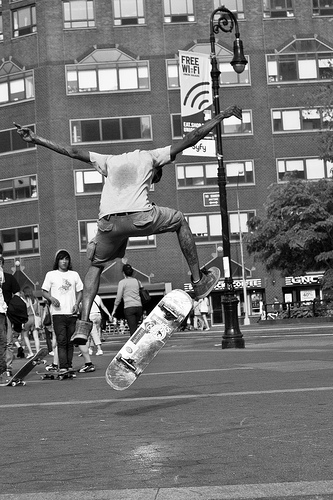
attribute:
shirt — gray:
[86, 133, 179, 232]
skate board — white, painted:
[104, 288, 192, 390]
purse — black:
[137, 284, 155, 307]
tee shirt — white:
[46, 270, 81, 310]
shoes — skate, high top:
[188, 262, 223, 301]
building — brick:
[0, 0, 332, 323]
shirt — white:
[65, 144, 189, 232]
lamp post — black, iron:
[195, 12, 268, 362]